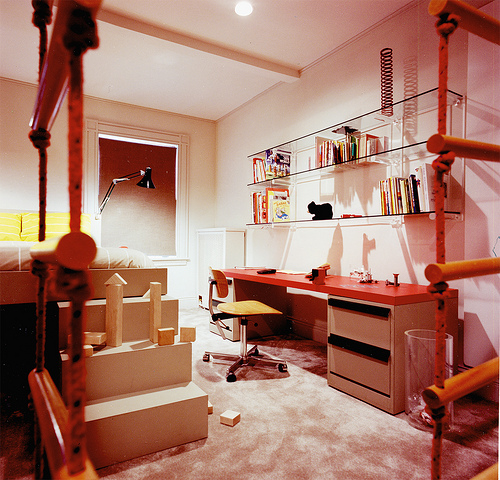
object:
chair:
[202, 266, 288, 382]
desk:
[208, 269, 459, 417]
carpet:
[270, 411, 300, 456]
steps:
[74, 380, 209, 468]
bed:
[0, 212, 168, 296]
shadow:
[470, 422, 489, 439]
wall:
[480, 287, 493, 311]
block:
[110, 416, 155, 456]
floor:
[342, 439, 356, 453]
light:
[235, 0, 255, 16]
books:
[383, 175, 411, 214]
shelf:
[243, 89, 462, 227]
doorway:
[94, 138, 180, 252]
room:
[0, 0, 500, 479]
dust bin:
[405, 329, 453, 434]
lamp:
[135, 167, 156, 189]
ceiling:
[333, 6, 353, 13]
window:
[98, 135, 177, 256]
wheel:
[226, 374, 237, 382]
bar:
[433, 0, 460, 136]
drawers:
[322, 294, 388, 354]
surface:
[276, 274, 306, 281]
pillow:
[19, 213, 92, 240]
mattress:
[0, 238, 153, 270]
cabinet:
[11, 277, 40, 307]